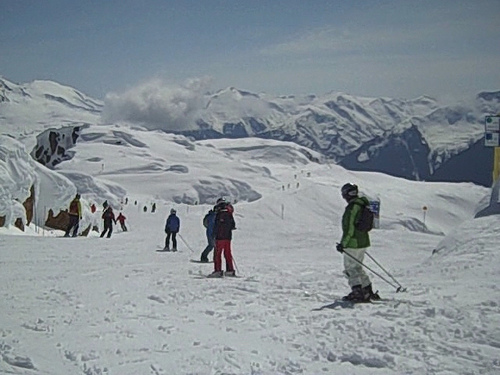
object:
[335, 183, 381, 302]
person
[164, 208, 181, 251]
person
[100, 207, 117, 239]
person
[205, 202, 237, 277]
person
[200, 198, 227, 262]
person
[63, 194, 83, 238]
person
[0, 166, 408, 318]
skiing